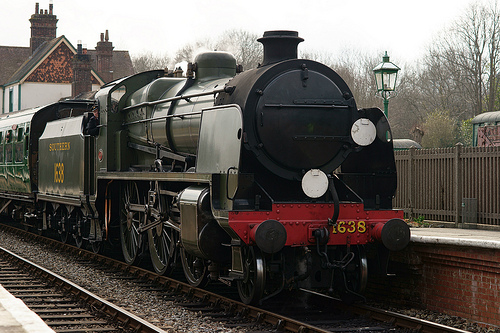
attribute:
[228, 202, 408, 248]
bumper — red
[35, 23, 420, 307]
train car — for fuel, for coal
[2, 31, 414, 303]
train — old, black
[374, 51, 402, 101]
light fixture — attractive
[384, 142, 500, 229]
fence — tight, brown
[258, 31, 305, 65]
smoke stack — black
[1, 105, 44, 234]
car — green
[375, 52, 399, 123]
lamppost — green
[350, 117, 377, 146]
circle — round